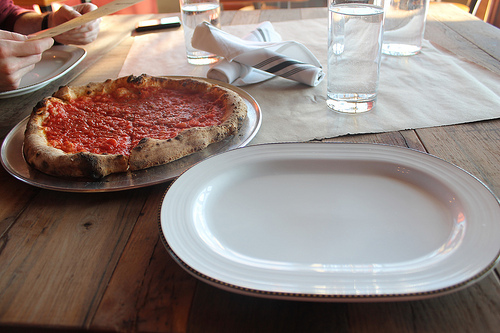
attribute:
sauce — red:
[40, 86, 233, 151]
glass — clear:
[377, 0, 427, 57]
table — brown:
[6, 199, 138, 329]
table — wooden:
[3, 1, 495, 326]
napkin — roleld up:
[190, 21, 323, 88]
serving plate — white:
[158, 140, 498, 305]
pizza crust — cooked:
[16, 144, 133, 179]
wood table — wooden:
[4, 2, 494, 329]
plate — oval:
[148, 118, 465, 306]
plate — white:
[153, 126, 498, 301]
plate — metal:
[0, 67, 266, 197]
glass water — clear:
[322, 1, 382, 120]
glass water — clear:
[388, 0, 438, 69]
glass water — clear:
[164, 2, 212, 76]